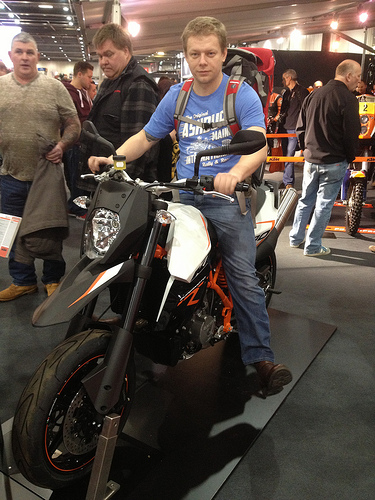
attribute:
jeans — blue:
[287, 152, 350, 248]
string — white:
[75, 87, 86, 110]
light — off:
[84, 206, 120, 259]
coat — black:
[294, 72, 371, 167]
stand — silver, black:
[0, 302, 342, 498]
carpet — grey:
[301, 265, 366, 478]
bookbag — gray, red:
[166, 74, 251, 143]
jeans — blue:
[163, 173, 315, 361]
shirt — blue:
[142, 70, 265, 193]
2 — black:
[360, 100, 372, 115]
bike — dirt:
[336, 89, 370, 234]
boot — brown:
[251, 355, 296, 399]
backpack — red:
[173, 45, 282, 146]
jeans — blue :
[214, 201, 288, 400]